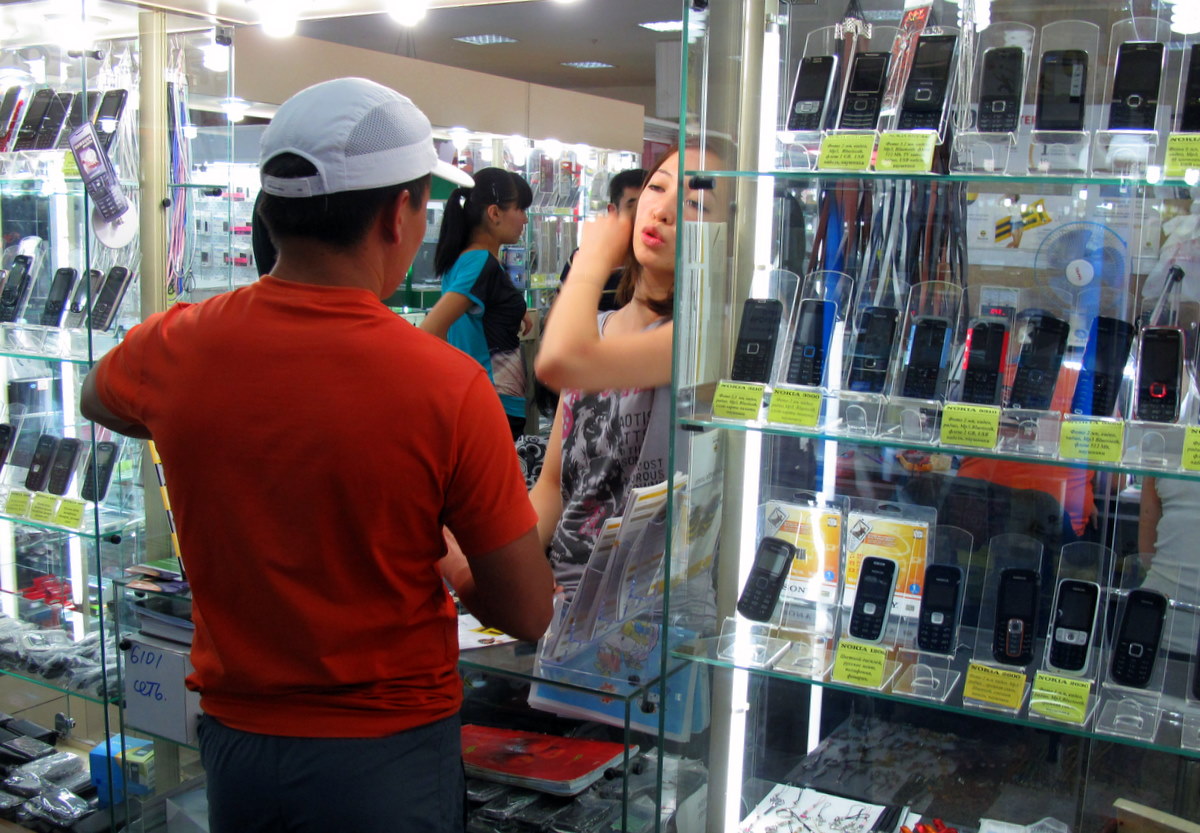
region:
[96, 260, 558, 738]
Man wearing a shirt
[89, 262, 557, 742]
Man wearing an orange shirt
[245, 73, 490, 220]
Man is wearing a hat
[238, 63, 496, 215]
Man wearing a white hat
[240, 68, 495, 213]
Man is wearing a white hat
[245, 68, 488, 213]
Man wearing a white cap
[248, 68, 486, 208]
Man is wearing a white cap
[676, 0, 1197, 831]
a glass case full of mobile phones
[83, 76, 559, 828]
a man at a window of a cell phone store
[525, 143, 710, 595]
a woman at a window of a cell phone store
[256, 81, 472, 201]
a white baseball cap on a man's head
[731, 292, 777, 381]
a mobile phone in a plastic case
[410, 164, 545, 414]
a woman in a mobile phone store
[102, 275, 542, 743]
a red shirt on a man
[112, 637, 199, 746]
a white card board box on a counter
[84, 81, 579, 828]
Man is standing in store that sells cell phones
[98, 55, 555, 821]
Man standing in a store is wearing a white hat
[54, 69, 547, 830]
Man standing in a store is wearing an orange shirt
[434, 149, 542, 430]
Woman standing in store is wearing a blue and black shirt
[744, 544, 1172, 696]
Row of black cell phones in a glass display case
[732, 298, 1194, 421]
Row of cell phones in a glass display case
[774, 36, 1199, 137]
Row of cell phones in a glass display case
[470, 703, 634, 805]
Red book on shelf in glass counter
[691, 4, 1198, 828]
Glass display case has three rows of cell phones on display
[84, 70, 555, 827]
the man wearing a hat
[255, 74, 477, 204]
the hat is white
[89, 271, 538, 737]
the shirt is red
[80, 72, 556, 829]
the man wearing the red shirt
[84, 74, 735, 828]
the woman talking to the man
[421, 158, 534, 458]
the woman is walking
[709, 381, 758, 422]
the paper is small and yellow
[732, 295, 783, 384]
the cell phone is black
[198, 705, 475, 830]
the pants are dark blue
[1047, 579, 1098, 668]
black cell phone in the display case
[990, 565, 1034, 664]
black cell phone in the display case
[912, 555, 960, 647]
black cell phone in the display case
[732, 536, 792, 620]
black cell phone in the display case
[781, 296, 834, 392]
black cell phone in the display case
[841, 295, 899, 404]
black cell phone in the display case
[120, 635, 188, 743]
white and blue sign on glass counter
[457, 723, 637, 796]
red notebook under glass counter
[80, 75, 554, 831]
man in red short sleeved shirt wears white cap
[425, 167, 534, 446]
woman with long dark ponytail wears blue top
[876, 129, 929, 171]
square yellow tag in clear case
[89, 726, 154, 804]
small blue box on bottom shelf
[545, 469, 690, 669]
stack of white and yellow papers in clear stand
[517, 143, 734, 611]
woman with brown hair wears gray shirt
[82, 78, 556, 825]
man in gray pants behind glass counter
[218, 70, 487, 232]
a white baseball hat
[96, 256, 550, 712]
man wearing a red shirt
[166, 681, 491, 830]
a blue pair of pants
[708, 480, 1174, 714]
a row of phones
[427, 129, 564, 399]
woman in the background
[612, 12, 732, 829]
a glass partition wall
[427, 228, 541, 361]
a blue and black shirt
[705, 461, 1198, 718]
a row of phones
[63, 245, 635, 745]
man wearing a red shirt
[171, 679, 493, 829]
a pair of blue jeans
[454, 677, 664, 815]
red book on the counter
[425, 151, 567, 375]
woman in the background